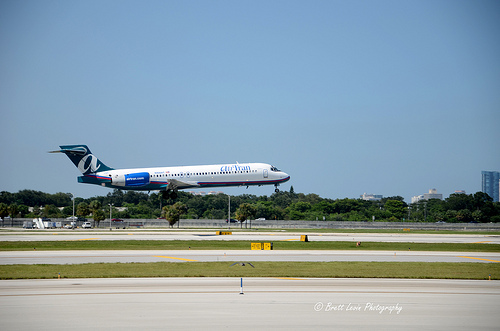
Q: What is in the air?
A: Airplane.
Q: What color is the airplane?
A: Blue and White.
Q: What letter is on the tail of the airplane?
A: A.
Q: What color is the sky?
A: Blue.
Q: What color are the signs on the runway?
A: Yellow.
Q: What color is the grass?
A: Green.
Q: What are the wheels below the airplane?
A: Landing Gear.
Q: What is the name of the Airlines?
A: Airtran.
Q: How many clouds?
A: Zero.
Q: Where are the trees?
A: Behind the wall.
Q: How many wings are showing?
A: 1.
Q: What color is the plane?
A: White and blue.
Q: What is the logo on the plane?
A: AirTran.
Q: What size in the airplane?
A: Small.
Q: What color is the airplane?
A: Red, white and blue.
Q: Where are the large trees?
A: Along the back.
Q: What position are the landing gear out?
A: Out.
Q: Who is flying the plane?
A: The pilot.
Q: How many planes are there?
A: One.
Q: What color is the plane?
A: White.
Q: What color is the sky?
A: Blue.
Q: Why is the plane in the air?
A: It's taking off.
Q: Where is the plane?
A: At the airport.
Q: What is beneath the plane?
A: The runway.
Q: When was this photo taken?
A: During the day.